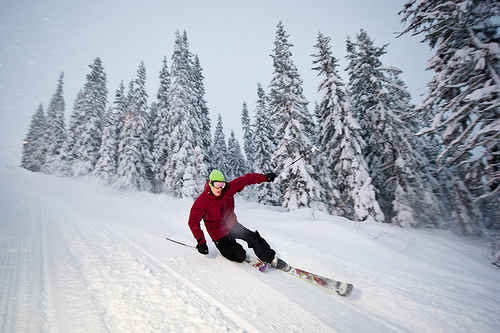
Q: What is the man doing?
A: Skiing.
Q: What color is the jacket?
A: Red.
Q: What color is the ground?
A: White.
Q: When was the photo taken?
A: Daytime.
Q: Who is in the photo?
A: A man.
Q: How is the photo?
A: Clear.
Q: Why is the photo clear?
A: Its during the day.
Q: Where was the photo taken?
A: On a ski slope.